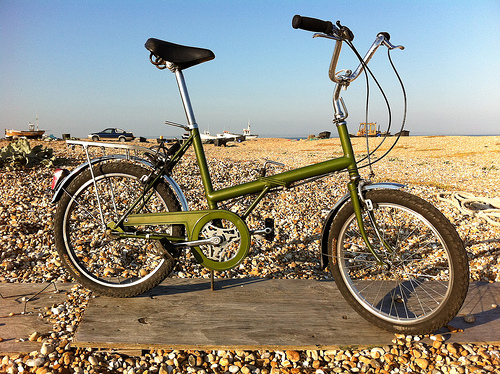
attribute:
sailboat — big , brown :
[8, 125, 43, 139]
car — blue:
[82, 124, 140, 142]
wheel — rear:
[45, 173, 167, 276]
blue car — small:
[85, 127, 135, 144]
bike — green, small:
[49, 14, 471, 335]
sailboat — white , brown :
[1, 97, 73, 168]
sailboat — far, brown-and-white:
[185, 124, 248, 143]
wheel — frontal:
[315, 182, 467, 336]